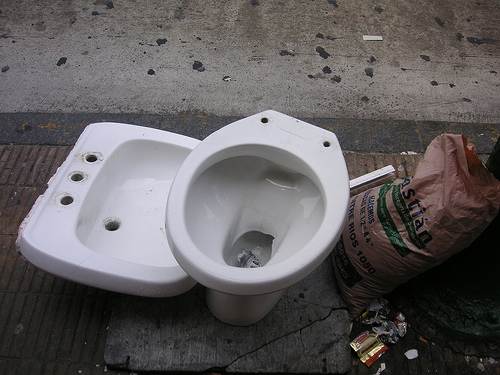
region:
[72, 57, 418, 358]
a toilet that is outside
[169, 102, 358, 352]
a white toilet outisde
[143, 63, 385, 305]
a bathroom toilet outside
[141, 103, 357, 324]
a white bathroom toilet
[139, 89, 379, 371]
a white bathroom toilet outside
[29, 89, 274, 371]
a bathroom sink outside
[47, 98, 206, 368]
a white sink outside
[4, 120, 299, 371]
a white bathroom sink outside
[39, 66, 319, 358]
a sink that is white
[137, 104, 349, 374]
a toilet that is white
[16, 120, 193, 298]
sink to the left of toilet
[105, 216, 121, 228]
drain hole in sink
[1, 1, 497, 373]
toilet is outside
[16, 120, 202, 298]
sink laying on pavement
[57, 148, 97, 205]
three holes drilled into sink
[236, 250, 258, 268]
gtay object inside toilet bowl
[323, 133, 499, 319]
brown bag to the right of toilet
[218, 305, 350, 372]
crack in front of toilet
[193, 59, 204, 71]
black spot on top of pavement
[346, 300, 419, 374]
litter next to bag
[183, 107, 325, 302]
A white toilet seat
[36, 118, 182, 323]
A white toilet sink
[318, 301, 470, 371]
A dirty litered ground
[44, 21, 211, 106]
A dirty litered ground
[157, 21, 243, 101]
A dirty litered ground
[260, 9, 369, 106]
A dirty litered ground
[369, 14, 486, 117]
A dirty litered ground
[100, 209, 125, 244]
A whole on a white sink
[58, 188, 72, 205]
A whole on a white sink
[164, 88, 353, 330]
White porcelain toilet bottom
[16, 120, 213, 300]
White porcelain sink top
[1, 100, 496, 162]
Dark line next to sidewalk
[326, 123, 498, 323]
Brown and green plastic bag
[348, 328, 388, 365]
Gold and red plastic cover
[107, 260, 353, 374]
Cracked square grey cement block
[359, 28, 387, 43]
White paper strip on street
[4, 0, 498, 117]
Grey and black road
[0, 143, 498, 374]
Grey grooved side walk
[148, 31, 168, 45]
Black spot on road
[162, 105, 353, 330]
white porcelain toilet bowl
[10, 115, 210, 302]
broken white porcelain bathroom sink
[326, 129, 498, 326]
large bag of mixable cement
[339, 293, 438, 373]
broken piece of electrical wiring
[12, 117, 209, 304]
white porcelain sink missing fixtures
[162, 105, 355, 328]
broken toilet bowl missing back of the toilet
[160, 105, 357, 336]
toilet bowl with an object floating in it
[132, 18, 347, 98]
stained concrete floor with black spots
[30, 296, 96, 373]
concrete flooring with grate pattern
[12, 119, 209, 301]
bathroom sink that is disconnected from a wall